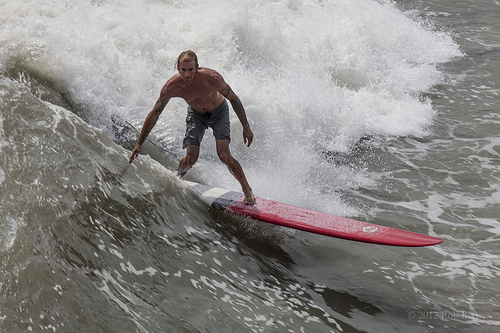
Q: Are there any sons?
A: No, there are no sons.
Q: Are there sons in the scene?
A: No, there are no sons.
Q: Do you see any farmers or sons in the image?
A: No, there are no sons or farmers.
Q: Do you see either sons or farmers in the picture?
A: No, there are no sons or farmers.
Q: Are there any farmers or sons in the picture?
A: No, there are no sons or farmers.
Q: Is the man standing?
A: Yes, the man is standing.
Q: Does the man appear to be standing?
A: Yes, the man is standing.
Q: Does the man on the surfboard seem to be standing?
A: Yes, the man is standing.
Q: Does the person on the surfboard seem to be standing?
A: Yes, the man is standing.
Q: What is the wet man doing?
A: The man is standing.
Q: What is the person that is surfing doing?
A: The man is standing.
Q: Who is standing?
A: The man is standing.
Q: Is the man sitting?
A: No, the man is standing.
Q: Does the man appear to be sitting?
A: No, the man is standing.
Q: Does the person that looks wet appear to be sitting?
A: No, the man is standing.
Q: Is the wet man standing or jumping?
A: The man is standing.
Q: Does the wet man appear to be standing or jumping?
A: The man is standing.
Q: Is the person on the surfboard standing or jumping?
A: The man is standing.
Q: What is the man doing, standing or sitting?
A: The man is standing.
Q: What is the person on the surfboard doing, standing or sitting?
A: The man is standing.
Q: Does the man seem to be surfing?
A: Yes, the man is surfing.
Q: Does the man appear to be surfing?
A: Yes, the man is surfing.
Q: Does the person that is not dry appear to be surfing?
A: Yes, the man is surfing.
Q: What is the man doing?
A: The man is surfing.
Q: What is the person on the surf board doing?
A: The man is surfing.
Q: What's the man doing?
A: The man is surfing.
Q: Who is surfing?
A: The man is surfing.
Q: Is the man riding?
A: No, the man is surfing.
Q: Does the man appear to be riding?
A: No, the man is surfing.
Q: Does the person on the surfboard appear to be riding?
A: No, the man is surfing.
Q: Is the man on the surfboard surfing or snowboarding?
A: The man is surfing.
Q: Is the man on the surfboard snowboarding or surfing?
A: The man is surfing.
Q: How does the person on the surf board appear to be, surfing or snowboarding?
A: The man is surfing.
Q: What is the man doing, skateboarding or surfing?
A: The man is surfing.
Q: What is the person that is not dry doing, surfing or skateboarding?
A: The man is surfing.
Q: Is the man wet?
A: Yes, the man is wet.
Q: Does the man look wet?
A: Yes, the man is wet.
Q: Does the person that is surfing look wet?
A: Yes, the man is wet.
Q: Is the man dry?
A: No, the man is wet.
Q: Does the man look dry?
A: No, the man is wet.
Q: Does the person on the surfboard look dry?
A: No, the man is wet.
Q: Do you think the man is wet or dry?
A: The man is wet.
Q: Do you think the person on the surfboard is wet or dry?
A: The man is wet.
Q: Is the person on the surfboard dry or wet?
A: The man is wet.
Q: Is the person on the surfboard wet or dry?
A: The man is wet.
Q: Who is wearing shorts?
A: The man is wearing shorts.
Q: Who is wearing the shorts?
A: The man is wearing shorts.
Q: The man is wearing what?
A: The man is wearing shorts.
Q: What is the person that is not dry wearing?
A: The man is wearing shorts.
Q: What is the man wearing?
A: The man is wearing shorts.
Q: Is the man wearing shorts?
A: Yes, the man is wearing shorts.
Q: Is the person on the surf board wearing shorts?
A: Yes, the man is wearing shorts.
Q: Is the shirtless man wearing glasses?
A: No, the man is wearing shorts.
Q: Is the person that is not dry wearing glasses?
A: No, the man is wearing shorts.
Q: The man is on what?
A: The man is on the surfboard.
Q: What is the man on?
A: The man is on the surfboard.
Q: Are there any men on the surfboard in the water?
A: Yes, there is a man on the surfboard.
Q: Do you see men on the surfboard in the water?
A: Yes, there is a man on the surfboard.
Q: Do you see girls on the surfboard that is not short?
A: No, there is a man on the surfboard.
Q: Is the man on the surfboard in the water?
A: Yes, the man is on the surfboard.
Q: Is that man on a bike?
A: No, the man is on the surfboard.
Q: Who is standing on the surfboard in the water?
A: The man is standing on the surfboard.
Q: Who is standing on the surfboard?
A: The man is standing on the surfboard.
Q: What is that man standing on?
A: The man is standing on the surfboard.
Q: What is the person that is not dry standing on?
A: The man is standing on the surfboard.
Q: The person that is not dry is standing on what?
A: The man is standing on the surfboard.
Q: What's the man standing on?
A: The man is standing on the surfboard.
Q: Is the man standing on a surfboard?
A: Yes, the man is standing on a surfboard.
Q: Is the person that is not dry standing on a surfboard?
A: Yes, the man is standing on a surfboard.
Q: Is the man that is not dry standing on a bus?
A: No, the man is standing on a surfboard.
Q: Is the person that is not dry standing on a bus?
A: No, the man is standing on a surfboard.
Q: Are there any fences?
A: No, there are no fences.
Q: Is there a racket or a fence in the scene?
A: No, there are no fences or rackets.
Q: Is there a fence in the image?
A: No, there are no fences.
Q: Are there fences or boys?
A: No, there are no fences or boys.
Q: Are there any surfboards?
A: Yes, there is a surfboard.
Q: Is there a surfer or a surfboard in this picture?
A: Yes, there is a surfboard.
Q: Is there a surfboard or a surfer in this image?
A: Yes, there is a surfboard.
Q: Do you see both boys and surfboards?
A: No, there is a surfboard but no boys.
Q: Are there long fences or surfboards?
A: Yes, there is a long surfboard.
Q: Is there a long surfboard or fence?
A: Yes, there is a long surfboard.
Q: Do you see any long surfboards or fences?
A: Yes, there is a long surfboard.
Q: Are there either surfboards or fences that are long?
A: Yes, the surfboard is long.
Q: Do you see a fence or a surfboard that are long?
A: Yes, the surfboard is long.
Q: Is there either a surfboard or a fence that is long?
A: Yes, the surfboard is long.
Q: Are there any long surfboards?
A: Yes, there is a long surfboard.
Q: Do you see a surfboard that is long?
A: Yes, there is a surfboard that is long.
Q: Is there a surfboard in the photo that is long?
A: Yes, there is a surfboard that is long.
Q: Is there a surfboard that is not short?
A: Yes, there is a long surfboard.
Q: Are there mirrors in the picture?
A: No, there are no mirrors.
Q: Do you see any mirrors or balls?
A: No, there are no mirrors or balls.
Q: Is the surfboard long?
A: Yes, the surfboard is long.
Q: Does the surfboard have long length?
A: Yes, the surfboard is long.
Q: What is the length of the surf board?
A: The surf board is long.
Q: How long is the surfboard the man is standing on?
A: The surf board is long.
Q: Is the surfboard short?
A: No, the surfboard is long.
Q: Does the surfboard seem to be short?
A: No, the surfboard is long.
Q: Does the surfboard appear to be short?
A: No, the surfboard is long.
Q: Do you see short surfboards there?
A: No, there is a surfboard but it is long.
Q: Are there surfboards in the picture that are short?
A: No, there is a surfboard but it is long.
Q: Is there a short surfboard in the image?
A: No, there is a surfboard but it is long.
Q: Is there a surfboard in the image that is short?
A: No, there is a surfboard but it is long.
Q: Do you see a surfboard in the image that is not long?
A: No, there is a surfboard but it is long.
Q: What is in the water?
A: The surfboard is in the water.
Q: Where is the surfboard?
A: The surfboard is in the water.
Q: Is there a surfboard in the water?
A: Yes, there is a surfboard in the water.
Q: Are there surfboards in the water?
A: Yes, there is a surfboard in the water.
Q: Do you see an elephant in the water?
A: No, there is a surfboard in the water.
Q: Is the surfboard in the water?
A: Yes, the surfboard is in the water.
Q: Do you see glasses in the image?
A: No, there are no glasses.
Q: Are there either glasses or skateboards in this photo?
A: No, there are no glasses or skateboards.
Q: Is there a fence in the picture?
A: No, there are no fences.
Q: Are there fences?
A: No, there are no fences.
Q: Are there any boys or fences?
A: No, there are no fences or boys.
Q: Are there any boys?
A: No, there are no boys.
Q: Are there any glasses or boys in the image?
A: No, there are no boys or glasses.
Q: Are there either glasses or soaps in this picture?
A: No, there are no glasses or soaps.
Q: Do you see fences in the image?
A: No, there are no fences.